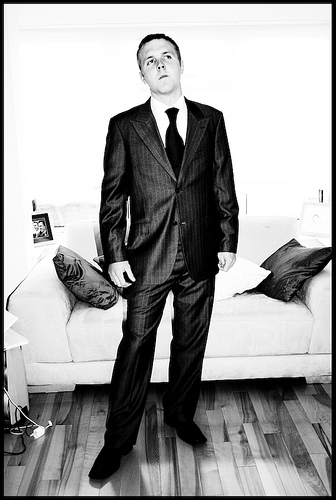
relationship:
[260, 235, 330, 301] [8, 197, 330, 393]
pillow across couch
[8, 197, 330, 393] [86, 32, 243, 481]
couch behind man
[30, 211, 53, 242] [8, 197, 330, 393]
picture frame near couch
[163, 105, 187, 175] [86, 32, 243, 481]
tie of man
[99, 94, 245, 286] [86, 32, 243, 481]
jacket of man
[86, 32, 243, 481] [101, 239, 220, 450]
man wearing pants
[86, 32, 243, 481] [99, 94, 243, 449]
man wearing suit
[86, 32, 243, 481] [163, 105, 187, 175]
man wearing tie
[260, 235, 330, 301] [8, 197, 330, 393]
pillow sitting on couch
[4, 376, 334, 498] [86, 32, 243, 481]
floor below man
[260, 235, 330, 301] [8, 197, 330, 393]
pillow laying on couch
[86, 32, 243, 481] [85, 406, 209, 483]
man wearing shoes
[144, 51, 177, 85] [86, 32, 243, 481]
face of man